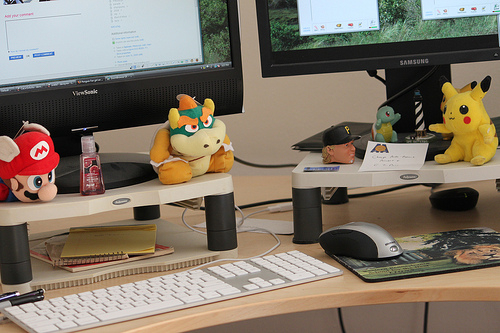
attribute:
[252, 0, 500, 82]
monitor — black, on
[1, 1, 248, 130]
monitor — on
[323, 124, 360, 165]
head — player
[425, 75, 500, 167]
animal — yellow, horned, red, black, stuffed, pikachu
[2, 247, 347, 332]
keyboard — white, silver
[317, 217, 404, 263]
mouse — black, silver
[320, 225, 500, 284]
pad — for computer, green, pile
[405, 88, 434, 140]
statue — lighthouse, small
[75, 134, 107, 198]
bottle — sanitizer, red, small, plastic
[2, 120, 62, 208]
toy — stuffed, mario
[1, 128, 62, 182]
hat — red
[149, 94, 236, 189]
figure — orange, red, green, yellow, white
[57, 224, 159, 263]
notepad — yellow